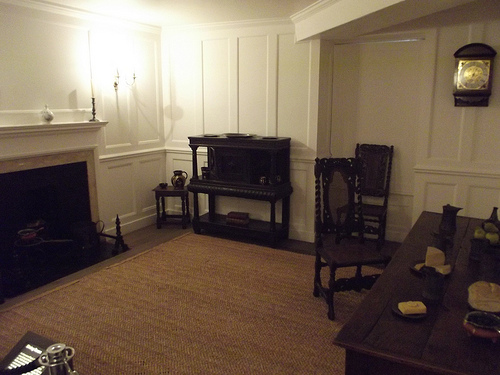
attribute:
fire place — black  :
[0, 160, 112, 268]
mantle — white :
[0, 117, 111, 164]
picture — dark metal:
[170, 169, 192, 195]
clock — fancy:
[451, 51, 488, 94]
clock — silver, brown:
[449, 42, 498, 107]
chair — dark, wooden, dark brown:
[311, 154, 392, 321]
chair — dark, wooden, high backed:
[315, 140, 430, 242]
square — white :
[397, 298, 427, 315]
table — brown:
[344, 210, 495, 369]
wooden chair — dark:
[314, 156, 384, 300]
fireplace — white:
[0, 145, 179, 288]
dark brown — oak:
[325, 248, 364, 261]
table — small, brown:
[144, 174, 201, 228]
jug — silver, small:
[160, 161, 198, 199]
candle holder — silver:
[88, 97, 98, 120]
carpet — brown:
[0, 221, 496, 370]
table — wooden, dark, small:
[152, 187, 195, 209]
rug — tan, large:
[1, 233, 398, 370]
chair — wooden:
[336, 140, 395, 249]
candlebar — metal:
[88, 95, 99, 120]